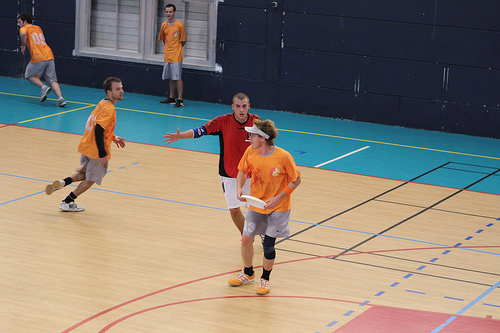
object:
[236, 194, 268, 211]
frisbee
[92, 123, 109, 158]
sleeve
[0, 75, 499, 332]
floor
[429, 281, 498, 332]
line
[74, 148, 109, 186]
short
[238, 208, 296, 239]
shorts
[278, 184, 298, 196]
band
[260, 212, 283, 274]
leging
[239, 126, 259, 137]
visor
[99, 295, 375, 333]
curved line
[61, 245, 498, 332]
curved line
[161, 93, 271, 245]
people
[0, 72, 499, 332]
basketball court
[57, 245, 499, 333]
red lines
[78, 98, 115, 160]
shirt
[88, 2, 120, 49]
window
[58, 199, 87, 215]
shoe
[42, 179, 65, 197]
shoe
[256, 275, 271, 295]
shoe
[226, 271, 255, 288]
shoe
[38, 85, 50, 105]
shoe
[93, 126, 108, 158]
black sleeve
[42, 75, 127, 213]
man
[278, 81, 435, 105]
line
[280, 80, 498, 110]
line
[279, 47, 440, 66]
line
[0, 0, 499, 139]
wall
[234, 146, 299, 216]
orange jersey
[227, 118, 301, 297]
man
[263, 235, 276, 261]
knee brace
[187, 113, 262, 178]
jersey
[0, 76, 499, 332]
surface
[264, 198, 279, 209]
hands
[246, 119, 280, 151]
head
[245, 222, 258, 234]
number